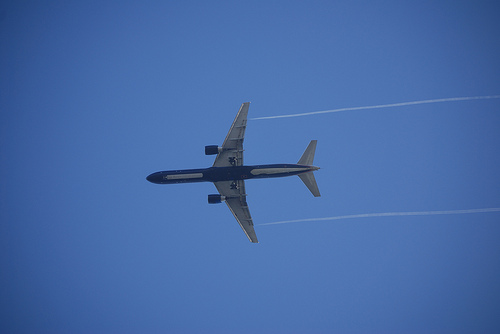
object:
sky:
[0, 0, 500, 332]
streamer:
[242, 90, 500, 122]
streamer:
[250, 203, 500, 231]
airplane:
[145, 102, 323, 244]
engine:
[203, 143, 229, 155]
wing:
[211, 100, 258, 168]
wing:
[213, 180, 262, 243]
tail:
[289, 139, 333, 202]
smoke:
[243, 90, 498, 124]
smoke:
[254, 205, 498, 228]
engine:
[206, 193, 229, 199]